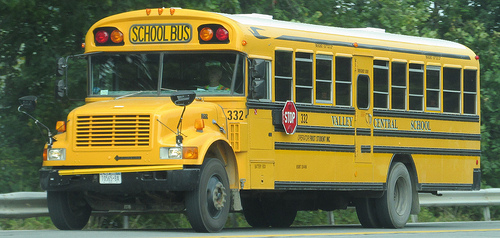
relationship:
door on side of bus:
[349, 53, 374, 163] [17, 7, 482, 234]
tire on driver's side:
[371, 161, 412, 229] [161, 10, 482, 232]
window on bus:
[313, 52, 335, 105] [40, 6, 487, 226]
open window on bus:
[295, 49, 316, 105] [40, 6, 487, 226]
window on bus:
[333, 52, 350, 107] [40, 6, 487, 226]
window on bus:
[272, 47, 292, 105] [40, 6, 487, 226]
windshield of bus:
[91, 49, 246, 96] [40, 6, 487, 226]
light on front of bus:
[200, 26, 227, 42] [40, 6, 487, 226]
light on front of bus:
[92, 23, 118, 44] [40, 6, 487, 226]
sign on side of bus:
[280, 100, 298, 135] [40, 6, 487, 226]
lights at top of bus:
[88, 18, 227, 46] [40, 6, 487, 226]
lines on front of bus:
[70, 109, 160, 153] [40, 6, 487, 226]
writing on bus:
[329, 111, 440, 131] [40, 6, 487, 226]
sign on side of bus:
[280, 100, 298, 135] [17, 7, 482, 234]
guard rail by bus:
[0, 183, 498, 232] [40, 6, 487, 226]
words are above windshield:
[123, 21, 205, 42] [82, 45, 249, 100]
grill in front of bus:
[76, 113, 151, 147] [17, 7, 482, 234]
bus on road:
[40, 6, 487, 226] [0, 218, 496, 235]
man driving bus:
[194, 62, 223, 91] [40, 6, 487, 226]